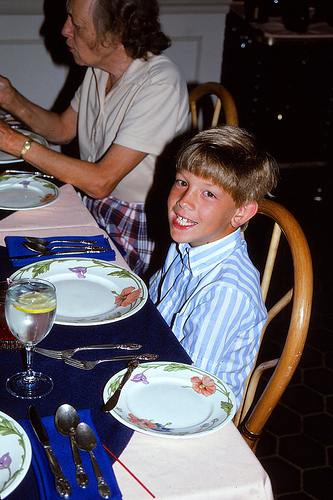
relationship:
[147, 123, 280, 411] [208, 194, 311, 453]
boy sits on chair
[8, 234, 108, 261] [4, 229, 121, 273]
utensil on napkin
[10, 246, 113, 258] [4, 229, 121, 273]
utensil on napkin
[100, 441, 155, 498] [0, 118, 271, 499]
straw on table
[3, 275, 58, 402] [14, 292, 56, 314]
water glass with wedge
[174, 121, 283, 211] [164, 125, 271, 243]
hair on head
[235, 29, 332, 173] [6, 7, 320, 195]
stove in background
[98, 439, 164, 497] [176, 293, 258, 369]
stick on cloth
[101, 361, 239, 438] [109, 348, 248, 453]
china with design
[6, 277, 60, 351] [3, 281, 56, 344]
glass with liquid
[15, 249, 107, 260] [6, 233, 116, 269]
silverwear on napkin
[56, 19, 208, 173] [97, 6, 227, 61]
woman with hair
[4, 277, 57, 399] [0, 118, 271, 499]
glass on table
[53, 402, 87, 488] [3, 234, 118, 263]
spoon on napkin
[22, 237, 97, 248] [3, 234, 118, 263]
spoon on napkin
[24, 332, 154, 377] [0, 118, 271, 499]
fork on table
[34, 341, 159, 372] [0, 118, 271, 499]
fork on table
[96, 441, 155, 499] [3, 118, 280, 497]
straw on cloth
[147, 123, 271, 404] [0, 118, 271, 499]
boy sitting at table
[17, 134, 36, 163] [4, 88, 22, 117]
gold watch on wrist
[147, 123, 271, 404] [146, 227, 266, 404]
boy wearing shirt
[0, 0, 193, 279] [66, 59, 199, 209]
woman wearing white shirt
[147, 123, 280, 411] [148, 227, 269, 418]
boy in shirt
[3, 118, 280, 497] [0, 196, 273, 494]
cloth on table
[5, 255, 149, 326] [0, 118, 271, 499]
plate on table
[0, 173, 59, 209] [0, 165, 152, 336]
plate on table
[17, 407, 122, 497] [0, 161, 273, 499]
napkin on table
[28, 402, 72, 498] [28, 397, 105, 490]
knife on napkin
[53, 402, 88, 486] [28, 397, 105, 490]
spoon on napkin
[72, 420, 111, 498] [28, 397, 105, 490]
spoon on napkin